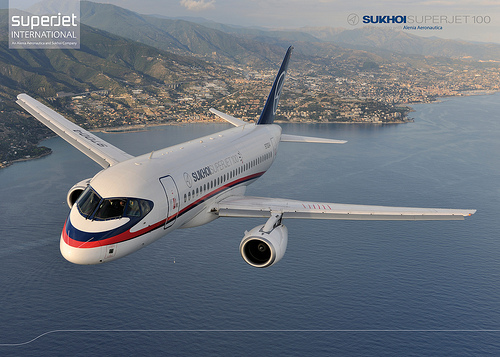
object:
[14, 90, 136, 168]
wing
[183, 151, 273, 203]
windows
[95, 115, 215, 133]
shote line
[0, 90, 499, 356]
ocean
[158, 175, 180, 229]
book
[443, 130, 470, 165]
ground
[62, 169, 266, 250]
stripes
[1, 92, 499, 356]
water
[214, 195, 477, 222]
wing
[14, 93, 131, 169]
large wing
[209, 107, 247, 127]
wing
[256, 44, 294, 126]
tail fin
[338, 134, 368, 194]
ground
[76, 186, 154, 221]
front window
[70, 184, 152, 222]
windows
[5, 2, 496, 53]
advertisement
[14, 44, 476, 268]
airplane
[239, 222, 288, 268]
engine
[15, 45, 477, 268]
plane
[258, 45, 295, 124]
tail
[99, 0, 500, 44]
clouds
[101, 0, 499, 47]
sky